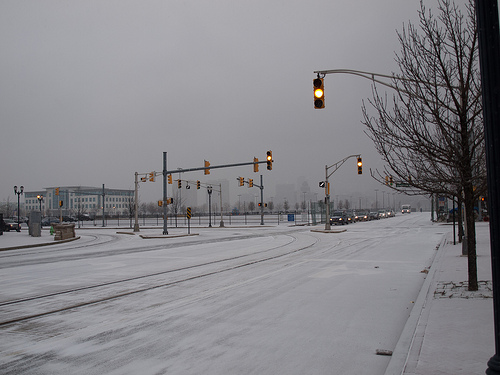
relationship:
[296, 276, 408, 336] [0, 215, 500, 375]
snow on road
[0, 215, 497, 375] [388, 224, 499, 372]
snow on path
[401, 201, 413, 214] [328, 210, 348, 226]
bus approaches car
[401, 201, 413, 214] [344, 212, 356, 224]
bus approaches car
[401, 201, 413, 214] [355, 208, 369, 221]
bus approaches car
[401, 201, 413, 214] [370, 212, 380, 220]
bus approaches car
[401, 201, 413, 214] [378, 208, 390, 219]
bus approaches car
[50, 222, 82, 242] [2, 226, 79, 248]
bin on curb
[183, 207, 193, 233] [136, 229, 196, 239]
traffic sign on corner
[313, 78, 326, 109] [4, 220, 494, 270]
light on intersection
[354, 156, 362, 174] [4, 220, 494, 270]
traffic light on intersection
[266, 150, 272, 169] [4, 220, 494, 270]
traffic light on intersection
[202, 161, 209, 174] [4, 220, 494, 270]
traffic light on intersection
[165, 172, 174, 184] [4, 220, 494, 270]
traffic light on intersection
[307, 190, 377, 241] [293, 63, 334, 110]
car is parked at light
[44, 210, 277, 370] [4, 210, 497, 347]
tracks are in snow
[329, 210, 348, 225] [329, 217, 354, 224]
car are shining headlights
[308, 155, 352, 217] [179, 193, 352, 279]
pole sits central in intersection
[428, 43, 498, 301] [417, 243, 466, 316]
trees standing inside pavement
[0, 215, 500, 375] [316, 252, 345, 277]
road covered in ice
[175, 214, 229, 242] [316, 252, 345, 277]
road covered in ice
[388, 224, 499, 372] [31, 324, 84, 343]
path near ice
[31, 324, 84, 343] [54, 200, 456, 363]
ice on road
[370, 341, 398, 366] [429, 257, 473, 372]
vent on sidewalk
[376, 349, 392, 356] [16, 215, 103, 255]
vent on sidewalk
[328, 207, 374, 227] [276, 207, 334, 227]
vent on sidewalk